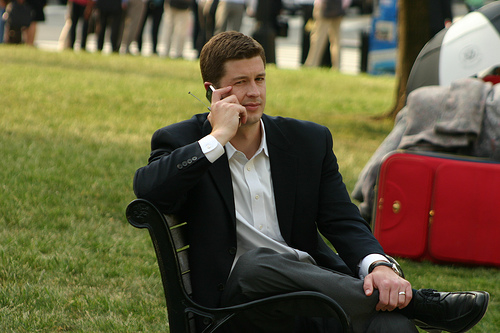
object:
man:
[130, 28, 491, 333]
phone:
[186, 84, 242, 129]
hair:
[198, 30, 268, 89]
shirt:
[129, 111, 389, 327]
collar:
[225, 118, 270, 166]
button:
[246, 167, 251, 171]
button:
[255, 195, 259, 200]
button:
[259, 225, 264, 230]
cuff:
[196, 133, 226, 165]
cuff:
[359, 253, 401, 281]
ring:
[398, 291, 407, 295]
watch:
[367, 259, 403, 277]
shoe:
[405, 286, 492, 333]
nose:
[245, 80, 260, 98]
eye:
[254, 77, 266, 82]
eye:
[232, 80, 248, 86]